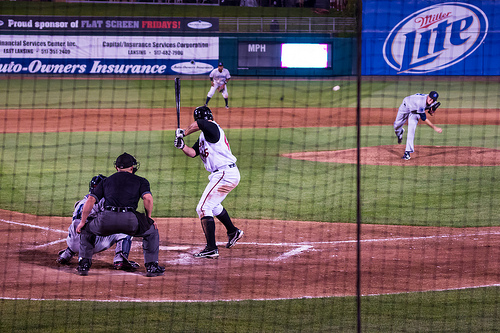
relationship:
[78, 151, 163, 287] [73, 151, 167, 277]
umpire behind umpire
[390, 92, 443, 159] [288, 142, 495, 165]
pitcher on mound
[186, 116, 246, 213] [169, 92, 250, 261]
uniform on batter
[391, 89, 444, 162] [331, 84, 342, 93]
pitcher throwing a baseball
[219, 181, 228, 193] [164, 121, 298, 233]
dirt on uniform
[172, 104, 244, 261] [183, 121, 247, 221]
batter wearing uniform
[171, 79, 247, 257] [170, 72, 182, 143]
batter holding black bat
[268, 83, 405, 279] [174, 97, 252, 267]
net behind batter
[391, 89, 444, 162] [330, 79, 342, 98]
pitcher tossing ball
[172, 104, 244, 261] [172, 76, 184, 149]
batter holding black bat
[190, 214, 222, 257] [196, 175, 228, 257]
sock on leg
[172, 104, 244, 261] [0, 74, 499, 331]
batter on baseball field